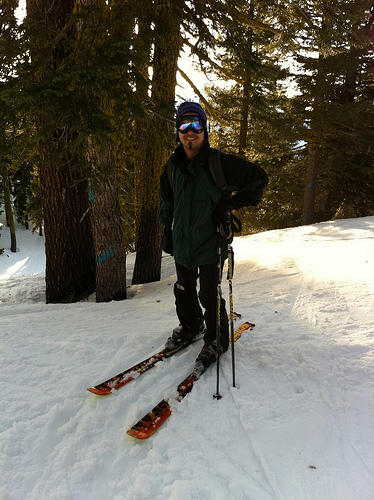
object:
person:
[155, 99, 269, 371]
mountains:
[239, 215, 374, 500]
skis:
[124, 320, 256, 442]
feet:
[194, 331, 230, 370]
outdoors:
[4, 8, 370, 494]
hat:
[174, 101, 208, 142]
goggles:
[176, 115, 207, 134]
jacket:
[158, 146, 269, 271]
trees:
[231, 0, 265, 238]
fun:
[180, 127, 201, 146]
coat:
[158, 143, 270, 266]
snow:
[0, 302, 84, 500]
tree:
[75, 0, 128, 303]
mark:
[95, 242, 120, 266]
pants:
[173, 262, 229, 341]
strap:
[208, 148, 227, 191]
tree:
[130, 0, 182, 286]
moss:
[142, 158, 161, 211]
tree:
[300, 0, 338, 225]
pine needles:
[278, 60, 283, 62]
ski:
[85, 310, 242, 397]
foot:
[165, 322, 203, 353]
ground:
[2, 216, 374, 500]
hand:
[213, 201, 234, 225]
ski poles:
[212, 220, 223, 400]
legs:
[165, 255, 204, 348]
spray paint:
[85, 181, 122, 266]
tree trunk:
[88, 100, 125, 302]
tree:
[0, 0, 150, 313]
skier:
[162, 98, 269, 381]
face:
[176, 115, 207, 151]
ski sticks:
[226, 233, 236, 389]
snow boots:
[197, 298, 229, 369]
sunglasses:
[178, 113, 205, 134]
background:
[2, 0, 374, 329]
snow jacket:
[158, 140, 269, 270]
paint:
[88, 186, 119, 266]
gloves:
[213, 198, 235, 227]